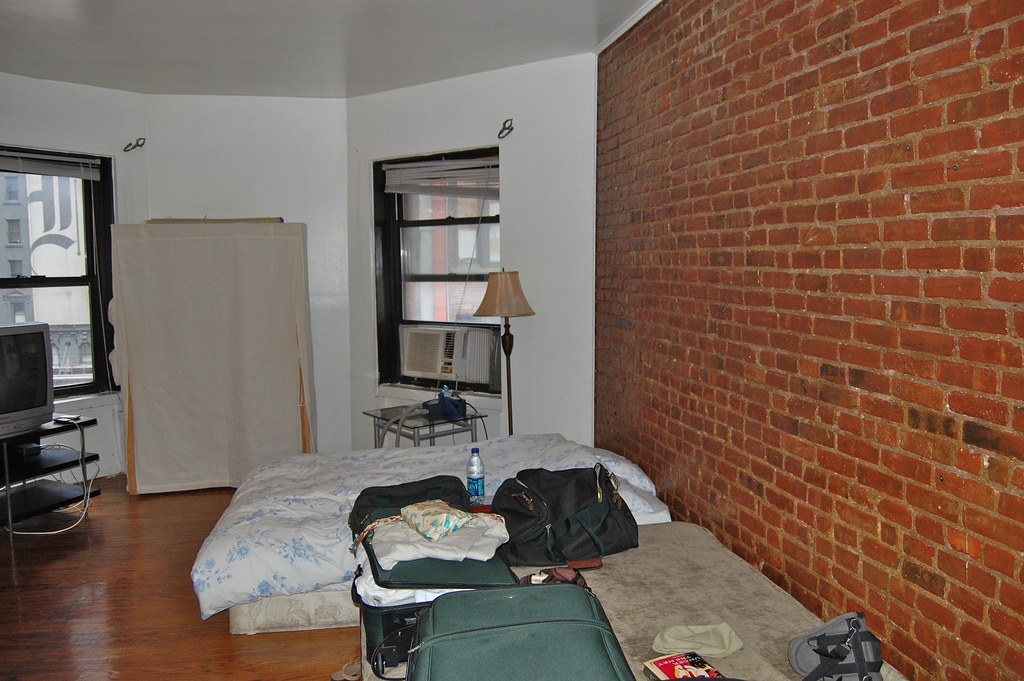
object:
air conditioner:
[397, 320, 504, 391]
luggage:
[406, 583, 634, 681]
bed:
[345, 520, 907, 680]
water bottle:
[466, 447, 485, 505]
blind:
[381, 154, 499, 201]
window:
[372, 150, 498, 388]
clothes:
[370, 499, 510, 572]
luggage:
[350, 470, 534, 680]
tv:
[0, 322, 58, 439]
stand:
[0, 400, 102, 537]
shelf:
[0, 444, 101, 487]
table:
[362, 400, 490, 449]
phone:
[421, 385, 467, 422]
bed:
[191, 433, 675, 636]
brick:
[884, 218, 930, 242]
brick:
[929, 216, 990, 241]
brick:
[904, 243, 962, 270]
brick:
[920, 273, 985, 300]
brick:
[890, 300, 944, 325]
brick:
[944, 306, 1012, 335]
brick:
[900, 328, 958, 356]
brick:
[884, 350, 934, 380]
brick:
[892, 378, 946, 412]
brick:
[857, 393, 906, 423]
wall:
[503, 50, 599, 445]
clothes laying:
[350, 475, 512, 589]